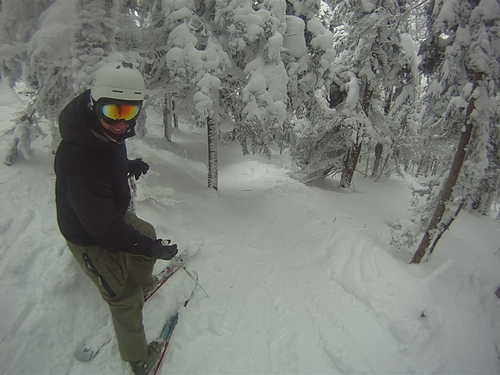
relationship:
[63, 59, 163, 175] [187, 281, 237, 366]
man on snow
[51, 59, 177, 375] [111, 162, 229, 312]
man on snow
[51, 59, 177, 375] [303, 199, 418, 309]
man skiing on snow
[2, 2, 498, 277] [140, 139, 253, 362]
trees covered in snow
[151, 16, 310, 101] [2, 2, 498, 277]
snow covering trees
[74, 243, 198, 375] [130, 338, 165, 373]
ski attached to a foot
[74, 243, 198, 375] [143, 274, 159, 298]
ski attached to a foot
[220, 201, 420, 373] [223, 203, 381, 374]
tracks in snow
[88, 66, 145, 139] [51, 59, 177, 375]
hard hat on a man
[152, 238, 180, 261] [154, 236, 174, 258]
gloved right on a hand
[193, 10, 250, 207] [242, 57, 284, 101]
tree covered with snow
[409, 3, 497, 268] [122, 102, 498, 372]
tree covered with snow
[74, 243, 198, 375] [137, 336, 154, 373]
ski on foot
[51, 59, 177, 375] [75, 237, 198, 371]
man wearing skis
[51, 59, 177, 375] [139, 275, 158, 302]
man has foot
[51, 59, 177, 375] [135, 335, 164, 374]
man has foot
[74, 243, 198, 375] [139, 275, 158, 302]
ski attached to foot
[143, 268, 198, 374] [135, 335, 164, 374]
ski attached to foot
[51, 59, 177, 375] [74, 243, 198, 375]
man standing on ski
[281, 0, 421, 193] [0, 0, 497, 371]
tree covered with snow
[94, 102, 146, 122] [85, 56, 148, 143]
goggles on head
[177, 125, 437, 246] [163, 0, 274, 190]
trail beside tree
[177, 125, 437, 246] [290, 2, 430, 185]
trail beside tree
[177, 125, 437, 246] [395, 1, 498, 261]
trail beside tree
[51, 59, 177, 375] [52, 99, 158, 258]
man wearing black coat